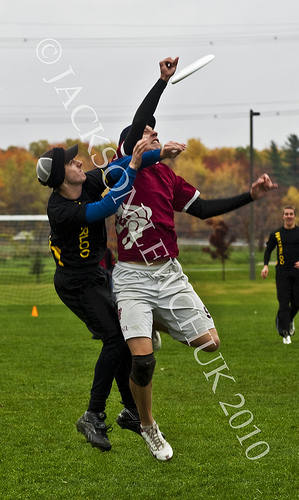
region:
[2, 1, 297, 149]
light of daytime sky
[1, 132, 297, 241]
autumn leaves on trees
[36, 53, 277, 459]
two men reaching for frisbee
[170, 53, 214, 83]
edge of white frisbee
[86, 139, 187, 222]
blue sleeves on arm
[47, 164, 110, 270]
black shirt with yellow design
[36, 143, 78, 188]
black band on baseball cap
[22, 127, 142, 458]
this is a person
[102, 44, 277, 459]
this is a person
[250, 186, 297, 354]
this is a person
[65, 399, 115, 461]
this is a sports shoe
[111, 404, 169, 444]
this is a sports shoe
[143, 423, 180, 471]
this is a sports shoe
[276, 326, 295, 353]
this is a sports shoe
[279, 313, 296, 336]
this is a sports shoe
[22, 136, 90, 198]
this is a cape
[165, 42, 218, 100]
this is a Frisbee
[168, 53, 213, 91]
white frisbee being caught mid air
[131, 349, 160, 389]
black knee support on man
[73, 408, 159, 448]
black tennis shoes on man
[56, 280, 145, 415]
man wearing black yoga pants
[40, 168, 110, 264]
man wearing black short sleeved t shirt with gold writing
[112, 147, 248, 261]
man wearing long sleeved t shirt in black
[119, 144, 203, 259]
man wearing maroon short sleeve tee shirt with white design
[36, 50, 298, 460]
thee men outdoors in field playing frisbee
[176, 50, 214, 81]
WHITE FRISBEE IN THE AIR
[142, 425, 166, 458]
WHITE SHOE ON THE FOOT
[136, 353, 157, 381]
BLACK KNEE SUPPORT ON LEG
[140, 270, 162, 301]
MAN WEARING GREY SHORTS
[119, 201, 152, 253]
WHITE IMAGE ON THE SHIRT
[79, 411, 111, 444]
MAN HAS ON BLACK SHOES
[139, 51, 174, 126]
BOY ARM UP IN THE AIR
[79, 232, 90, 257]
YELLOW WRITING ON THE SHIRT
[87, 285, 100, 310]
MAN WEARING BLACK PANTS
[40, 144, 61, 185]
BOY WEARING A CAP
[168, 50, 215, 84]
white frisbee in air by men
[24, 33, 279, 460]
water mark in white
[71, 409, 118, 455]
black cleats on mans foot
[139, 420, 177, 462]
white cleats on mans foot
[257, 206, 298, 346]
man in black cloths watchng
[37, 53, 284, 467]
two men fighting too catch frisbee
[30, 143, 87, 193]
sweat band on black and white cap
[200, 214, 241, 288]
small red tree in background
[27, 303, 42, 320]
orange cone behind players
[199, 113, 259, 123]
black electric lines going to pole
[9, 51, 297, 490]
the colors in this photo are so vivid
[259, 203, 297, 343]
a person is running in black dress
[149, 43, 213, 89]
a white frisbee in the air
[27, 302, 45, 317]
an orange caution cone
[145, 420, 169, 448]
a white shoe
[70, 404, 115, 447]
a black shoe on the foot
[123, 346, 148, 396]
a black knee pad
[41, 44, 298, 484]
people playing frisbee.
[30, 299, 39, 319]
An orange cone.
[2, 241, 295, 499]
A grassy field.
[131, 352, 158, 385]
A black knee brace.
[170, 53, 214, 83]
A white frisbee.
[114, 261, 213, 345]
Grey sports shorts.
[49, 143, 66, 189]
Black ear warmers.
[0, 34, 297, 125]
Power lines hanging above everything.